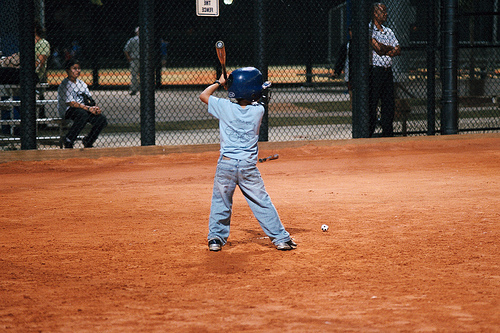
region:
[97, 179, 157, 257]
the clay on the ground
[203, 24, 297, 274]
the boy holding a bat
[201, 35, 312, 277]
the boy is young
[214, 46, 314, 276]
the boy wearing a helmet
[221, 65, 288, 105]
the helmet is blue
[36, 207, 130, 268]
the clay is brown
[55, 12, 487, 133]
the chain link fence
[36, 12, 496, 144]
the fence is made of metal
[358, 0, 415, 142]
the man is standing and watching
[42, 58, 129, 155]
the young boy is sitting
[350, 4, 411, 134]
a man watching baseball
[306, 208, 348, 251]
a small ball on the ground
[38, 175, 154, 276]
red dirt on the field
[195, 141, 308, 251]
a boy wearing jeans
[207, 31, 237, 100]
a baseball bat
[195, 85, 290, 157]
a light blue tee shirt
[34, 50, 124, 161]
a boy sitting on a bench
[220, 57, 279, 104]
a blue batters helmet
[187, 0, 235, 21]
a white sign on the fence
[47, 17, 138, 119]
a chain link fence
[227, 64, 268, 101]
Boy wears blue helmet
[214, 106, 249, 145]
Boy wears blue shirt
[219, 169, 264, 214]
Boy wears grey pants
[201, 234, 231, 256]
boy wears blue sneakers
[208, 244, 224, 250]
Grey bottoms on sneakers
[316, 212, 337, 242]
Ball in dirt of field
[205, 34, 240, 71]
Top of bat is brown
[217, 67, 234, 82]
Bottom of bat is black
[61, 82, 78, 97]
Boys shirt is grey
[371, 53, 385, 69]
Man wearing white shirt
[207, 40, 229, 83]
The bat in the batter's hand.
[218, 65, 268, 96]
The blue helmet the batter is wearing.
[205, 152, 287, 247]
The blue jeans the batter is wearing.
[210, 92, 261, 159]
The light blue t-shirt the batter is wearing.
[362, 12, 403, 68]
The man in the white shirt next to the chain linked fence on the right.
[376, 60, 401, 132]
The man on the right wearing black pants.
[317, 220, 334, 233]
The ball on the ground next to the boy.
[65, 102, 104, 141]
The black pants the boy sitting on the bleachers is wearing.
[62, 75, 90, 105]
The white t-shirt the boy sitting on the bleachers is wearing.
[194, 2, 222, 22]
The black and white sign on the chain linked fence.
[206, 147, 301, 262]
a boy wearing blue jeans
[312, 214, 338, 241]
a small ball on the ground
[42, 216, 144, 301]
red dirt on the field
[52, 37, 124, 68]
a chain link fence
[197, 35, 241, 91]
a bat in the boys hand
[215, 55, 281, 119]
a blue baseball helmet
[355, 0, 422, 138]
a man watching from the side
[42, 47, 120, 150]
a boy sitting on the bleachers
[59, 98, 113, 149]
dark pants on a boy